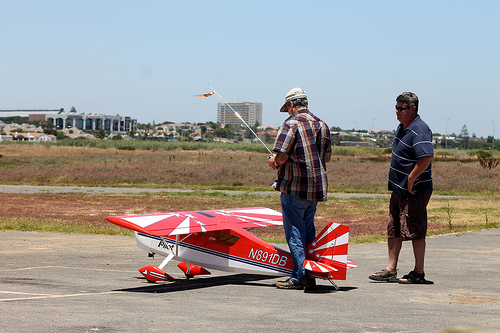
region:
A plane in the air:
[196, 88, 221, 100]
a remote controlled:
[219, 99, 271, 156]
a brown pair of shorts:
[386, 185, 432, 240]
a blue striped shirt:
[387, 122, 436, 193]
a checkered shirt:
[270, 111, 330, 203]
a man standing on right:
[367, 90, 438, 285]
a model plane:
[102, 200, 358, 289]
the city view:
[1, 95, 496, 147]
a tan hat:
[277, 85, 307, 110]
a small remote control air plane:
[105, 187, 352, 293]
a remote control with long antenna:
[195, 75, 287, 170]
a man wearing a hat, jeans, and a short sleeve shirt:
[255, 75, 345, 290]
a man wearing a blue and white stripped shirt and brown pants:
[367, 82, 433, 282]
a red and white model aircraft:
[103, 191, 358, 293]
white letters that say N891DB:
[243, 242, 296, 271]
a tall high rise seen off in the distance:
[211, 98, 267, 131]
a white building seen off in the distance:
[28, 105, 134, 143]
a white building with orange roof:
[6, 128, 58, 146]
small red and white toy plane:
[103, 195, 367, 302]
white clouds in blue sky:
[40, 23, 95, 55]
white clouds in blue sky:
[328, 47, 357, 78]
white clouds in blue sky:
[136, 30, 177, 76]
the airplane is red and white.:
[102, 203, 354, 294]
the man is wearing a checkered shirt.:
[271, 112, 332, 199]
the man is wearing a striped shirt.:
[390, 119, 433, 196]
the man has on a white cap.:
[281, 85, 311, 105]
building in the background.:
[216, 100, 256, 126]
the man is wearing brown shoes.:
[369, 268, 425, 285]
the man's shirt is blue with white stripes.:
[388, 117, 436, 196]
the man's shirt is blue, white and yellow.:
[271, 112, 330, 202]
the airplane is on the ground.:
[105, 211, 351, 293]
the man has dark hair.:
[396, 90, 418, 116]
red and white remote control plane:
[129, 193, 289, 325]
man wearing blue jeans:
[285, 194, 313, 244]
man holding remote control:
[233, 84, 275, 166]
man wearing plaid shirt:
[274, 122, 298, 163]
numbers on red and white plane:
[245, 235, 286, 280]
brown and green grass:
[128, 136, 167, 181]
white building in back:
[46, 101, 141, 151]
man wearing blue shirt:
[396, 148, 423, 176]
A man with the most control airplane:
[103, 71, 363, 303]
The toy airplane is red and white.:
[112, 195, 360, 303]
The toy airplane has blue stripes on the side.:
[143, 233, 298, 277]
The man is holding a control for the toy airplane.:
[196, 81, 276, 165]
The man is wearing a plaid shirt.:
[268, 110, 330, 200]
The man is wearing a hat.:
[279, 84, 309, 113]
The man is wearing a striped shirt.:
[368, 125, 440, 190]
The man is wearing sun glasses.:
[390, 103, 421, 113]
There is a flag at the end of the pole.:
[197, 86, 218, 101]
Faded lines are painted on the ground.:
[10, 256, 92, 306]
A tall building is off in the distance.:
[219, 96, 261, 128]